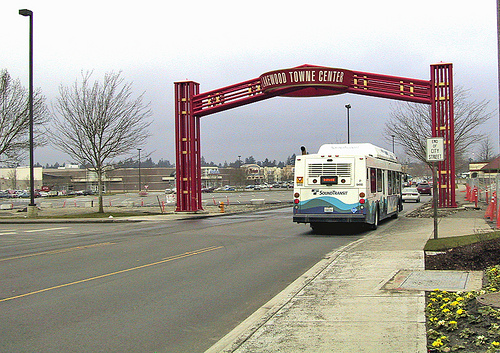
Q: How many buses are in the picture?
A: One.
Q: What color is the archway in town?
A: Red.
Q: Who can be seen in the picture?
A: No one.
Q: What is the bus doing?
A: Driving.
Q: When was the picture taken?
A: During the day.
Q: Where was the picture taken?
A: On the street.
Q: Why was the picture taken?
A: To capture the sign.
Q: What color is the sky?
A: Blue.